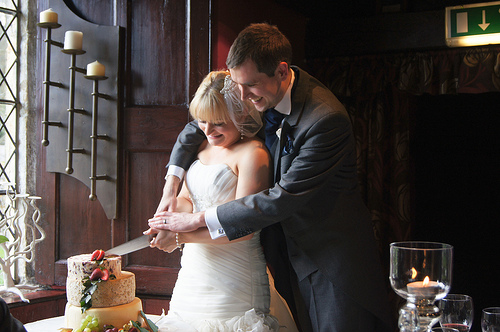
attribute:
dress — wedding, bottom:
[139, 159, 279, 329]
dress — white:
[189, 160, 274, 314]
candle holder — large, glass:
[387, 240, 462, 330]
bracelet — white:
[169, 228, 186, 252]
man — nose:
[217, 17, 397, 329]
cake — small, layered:
[64, 241, 145, 328]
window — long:
[0, 21, 34, 285]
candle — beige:
[86, 60, 103, 75]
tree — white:
[0, 185, 47, 303]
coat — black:
[306, 138, 349, 192]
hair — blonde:
[188, 65, 253, 125]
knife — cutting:
[44, 228, 159, 330]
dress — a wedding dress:
[154, 154, 278, 330]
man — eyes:
[223, 26, 385, 291]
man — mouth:
[248, 38, 367, 329]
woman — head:
[180, 84, 260, 326]